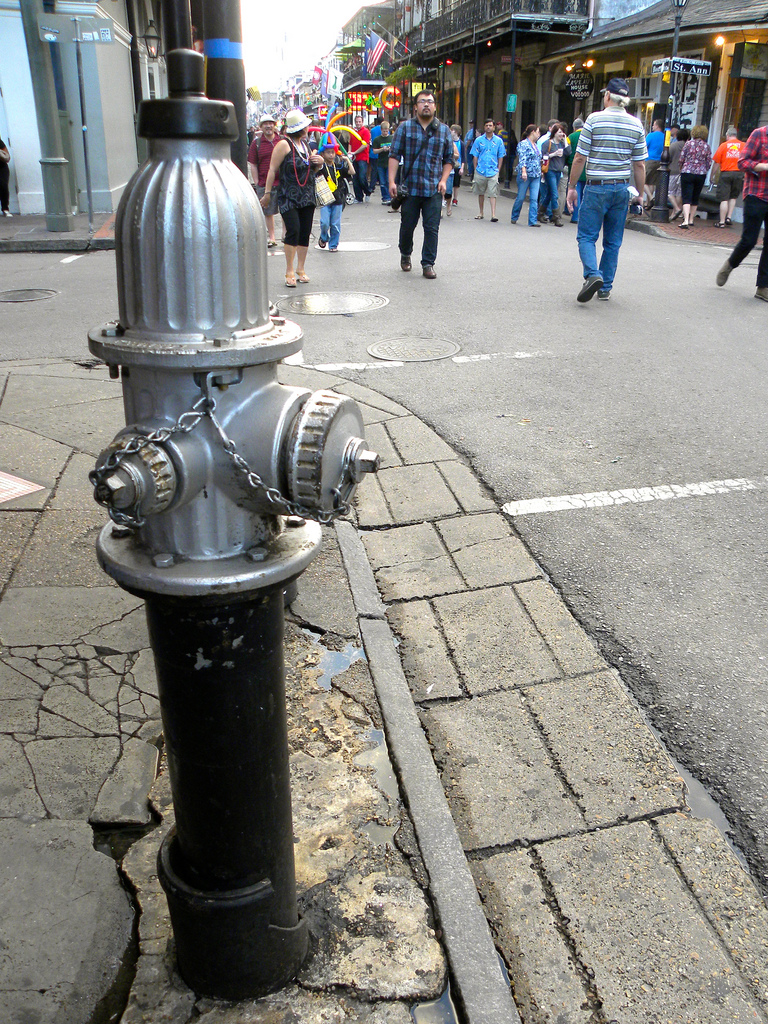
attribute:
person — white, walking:
[462, 104, 545, 243]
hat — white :
[247, 92, 379, 156]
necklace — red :
[267, 127, 345, 180]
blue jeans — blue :
[566, 171, 635, 288]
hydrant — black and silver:
[90, 39, 381, 1009]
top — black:
[136, 34, 254, 141]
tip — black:
[137, 45, 243, 138]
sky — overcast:
[237, 12, 414, 160]